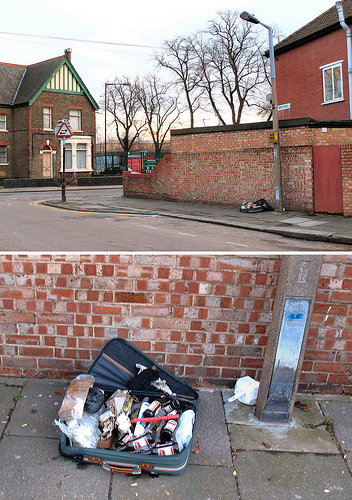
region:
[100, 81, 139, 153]
The tree is barren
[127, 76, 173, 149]
The tree is barren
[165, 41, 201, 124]
The tree is barren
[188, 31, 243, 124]
The tree is barren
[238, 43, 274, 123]
The tree is barren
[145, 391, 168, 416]
The bottle is dark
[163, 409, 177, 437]
The bottle is dark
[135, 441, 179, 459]
The bottle is dark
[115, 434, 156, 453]
The bottle is dark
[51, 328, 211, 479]
The suitcase is open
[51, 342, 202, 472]
the suitcase on the ground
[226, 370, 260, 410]
the white plastic bag on the sidewalk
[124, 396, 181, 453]
the bottles in the luggage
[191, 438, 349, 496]
the leaves on the sidewalk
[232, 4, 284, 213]
the streetlight on the siewalk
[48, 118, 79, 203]
the street sign on the corner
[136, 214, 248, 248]
the lines on the ground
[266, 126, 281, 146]
the yellow sign on the post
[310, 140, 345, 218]
the red gate on the red brick wall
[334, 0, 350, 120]
The chimney pipe on the wall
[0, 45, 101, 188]
Brick house with green and white trim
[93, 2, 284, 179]
Dead trees between the houses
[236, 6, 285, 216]
Street lamp next to the brick wall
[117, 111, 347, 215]
Brick wall next to the house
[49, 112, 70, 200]
Pole with a white street sign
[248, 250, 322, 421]
Bottom section of the street lamp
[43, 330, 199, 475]
Suitcase on the bottom with garbage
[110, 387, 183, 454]
Beer bottles in the suitcase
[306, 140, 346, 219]
Brown gate on the brick wall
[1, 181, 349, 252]
Street in between the houses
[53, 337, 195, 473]
an open suitcase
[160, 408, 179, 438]
a brown bottle of beer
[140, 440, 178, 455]
a brown bottle of beer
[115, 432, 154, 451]
a brown bottle of beer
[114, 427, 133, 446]
a brown bottle of beer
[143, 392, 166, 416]
a brown bottle of beer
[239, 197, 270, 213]
an open suitcase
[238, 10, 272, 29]
an overhead street light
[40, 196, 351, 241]
a grey paved sidewalk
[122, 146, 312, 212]
a long red brick wall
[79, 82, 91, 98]
the roof is green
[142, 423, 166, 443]
the suit case has bottles in it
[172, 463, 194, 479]
the suit caase is on the ground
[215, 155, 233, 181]
the wall is made of bricks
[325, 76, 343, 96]
the window has no curtains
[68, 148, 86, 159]
the curtains are closed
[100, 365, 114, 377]
the suit case is blue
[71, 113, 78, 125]
the blind is white